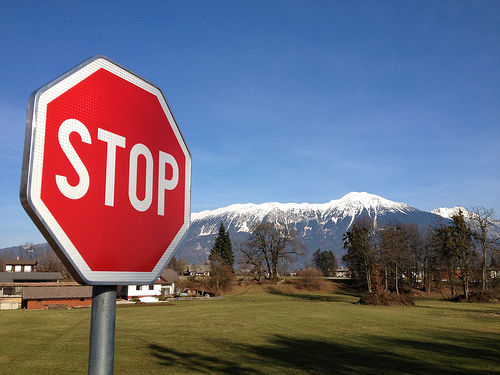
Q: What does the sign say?
A: Stop.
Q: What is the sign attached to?
A: A post.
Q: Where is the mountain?
A: In the distance.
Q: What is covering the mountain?
A: Snow.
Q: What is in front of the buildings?
A: A lawn.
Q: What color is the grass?
A: Green.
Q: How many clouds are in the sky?
A: None.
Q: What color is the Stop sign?
A: Red and white.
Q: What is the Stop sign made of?
A: Metal.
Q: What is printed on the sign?
A: Stop.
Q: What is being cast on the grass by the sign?
A: Shadow.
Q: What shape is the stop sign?
A: Octagon.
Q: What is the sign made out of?
A: Metal.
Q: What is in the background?
A: Mountains.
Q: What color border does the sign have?
A: White.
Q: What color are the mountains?
A: Grey and white.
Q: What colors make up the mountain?
A: Grey and white.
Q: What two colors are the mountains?
A: Grey and white.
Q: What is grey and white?
A: The mountains are grey and white.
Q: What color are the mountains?
A: The mountains are grey and white.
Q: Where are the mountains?
A: The mountains are behind the trees.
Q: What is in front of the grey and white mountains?
A: The trees are in-front of the grey and white mountains.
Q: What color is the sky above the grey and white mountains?
A: The sky is blue.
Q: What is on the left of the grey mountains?
A: Part of a red stop sign.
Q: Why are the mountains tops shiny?
A: The mountain tops are shiny because of the sun.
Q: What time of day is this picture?
A: This picture is during the day.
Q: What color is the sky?
A: The sky is blue.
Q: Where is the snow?
A: On top of the mountain.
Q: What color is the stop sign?
A: Red and white.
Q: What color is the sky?
A: Blue.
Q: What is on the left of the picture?
A: A house.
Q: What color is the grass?
A: Green.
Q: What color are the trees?
A: Green.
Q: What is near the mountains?
A: A small grove of trees.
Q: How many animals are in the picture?
A: 0.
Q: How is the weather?
A: Clear and sunny.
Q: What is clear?
A: Sky.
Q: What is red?
A: Sign.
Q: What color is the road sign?
A: Red.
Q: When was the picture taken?
A: Daytime.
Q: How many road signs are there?
A: One.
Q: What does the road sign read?
A: Stop.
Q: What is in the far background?
A: Mountains.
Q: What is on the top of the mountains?
A: Snow.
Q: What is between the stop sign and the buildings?
A: A field.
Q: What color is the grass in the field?
A: Green.